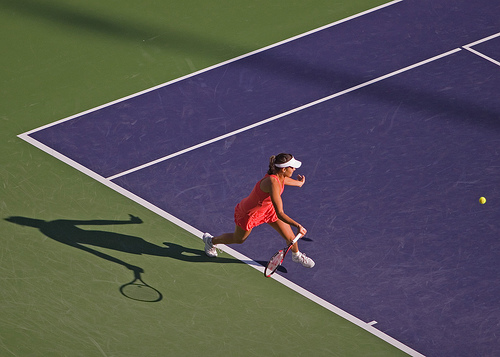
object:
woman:
[205, 151, 318, 269]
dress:
[231, 172, 291, 231]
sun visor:
[272, 152, 298, 170]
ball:
[478, 197, 488, 205]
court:
[0, 0, 499, 357]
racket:
[262, 228, 311, 277]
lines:
[14, 0, 401, 140]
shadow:
[21, 2, 500, 132]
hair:
[267, 147, 292, 175]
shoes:
[200, 230, 220, 259]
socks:
[291, 247, 308, 259]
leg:
[210, 215, 254, 245]